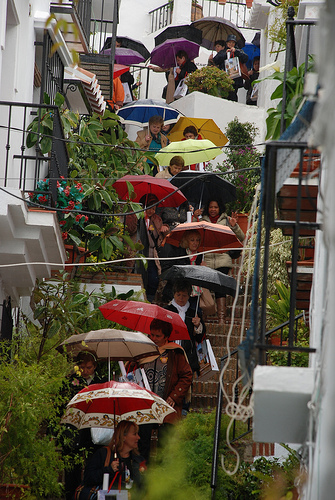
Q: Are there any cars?
A: No, there are no cars.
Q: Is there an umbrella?
A: Yes, there is an umbrella.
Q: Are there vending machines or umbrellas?
A: Yes, there is an umbrella.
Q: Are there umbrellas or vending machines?
A: Yes, there is an umbrella.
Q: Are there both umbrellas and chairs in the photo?
A: No, there is an umbrella but no chairs.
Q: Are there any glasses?
A: No, there are no glasses.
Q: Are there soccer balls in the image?
A: No, there are no soccer balls.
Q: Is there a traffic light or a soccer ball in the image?
A: No, there are no soccer balls or traffic lights.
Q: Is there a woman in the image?
A: Yes, there is a woman.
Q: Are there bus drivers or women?
A: Yes, there is a woman.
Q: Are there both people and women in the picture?
A: Yes, there are both a woman and a person.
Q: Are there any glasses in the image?
A: No, there are no glasses.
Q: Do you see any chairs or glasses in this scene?
A: No, there are no glasses or chairs.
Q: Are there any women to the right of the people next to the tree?
A: Yes, there is a woman to the right of the people.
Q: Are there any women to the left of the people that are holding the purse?
A: No, the woman is to the right of the people.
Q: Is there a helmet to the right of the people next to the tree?
A: No, there is a woman to the right of the people.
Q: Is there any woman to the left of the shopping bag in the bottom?
A: Yes, there is a woman to the left of the shopping bag.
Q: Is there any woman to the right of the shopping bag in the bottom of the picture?
A: No, the woman is to the left of the shopping bag.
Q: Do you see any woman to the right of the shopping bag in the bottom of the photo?
A: No, the woman is to the left of the shopping bag.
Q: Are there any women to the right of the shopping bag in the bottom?
A: No, the woman is to the left of the shopping bag.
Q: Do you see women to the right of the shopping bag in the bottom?
A: No, the woman is to the left of the shopping bag.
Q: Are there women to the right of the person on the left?
A: Yes, there is a woman to the right of the person.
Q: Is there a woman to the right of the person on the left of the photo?
A: Yes, there is a woman to the right of the person.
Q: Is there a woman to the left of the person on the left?
A: No, the woman is to the right of the person.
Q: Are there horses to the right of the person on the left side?
A: No, there is a woman to the right of the person.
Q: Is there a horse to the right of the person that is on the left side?
A: No, there is a woman to the right of the person.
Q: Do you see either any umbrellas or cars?
A: Yes, there is an umbrella.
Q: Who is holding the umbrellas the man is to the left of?
A: The people are holding the umbrellas.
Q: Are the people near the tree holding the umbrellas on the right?
A: Yes, the people are holding the umbrellas.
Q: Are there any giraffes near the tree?
A: No, there are people near the tree.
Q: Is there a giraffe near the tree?
A: No, there are people near the tree.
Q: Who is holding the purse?
A: The people are holding the purse.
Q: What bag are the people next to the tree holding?
A: The people are holding the purse.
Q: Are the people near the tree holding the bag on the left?
A: Yes, the people are holding the purse.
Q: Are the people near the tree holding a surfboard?
A: No, the people are holding the purse.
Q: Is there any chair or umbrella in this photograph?
A: Yes, there is an umbrella.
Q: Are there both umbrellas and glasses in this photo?
A: No, there is an umbrella but no glasses.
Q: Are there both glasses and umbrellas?
A: No, there is an umbrella but no glasses.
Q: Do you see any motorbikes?
A: No, there are no motorbikes.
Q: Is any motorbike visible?
A: No, there are no motorcycles.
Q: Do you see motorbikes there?
A: No, there are no motorbikes.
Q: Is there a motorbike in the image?
A: No, there are no motorcycles.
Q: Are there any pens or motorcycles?
A: No, there are no motorcycles or pens.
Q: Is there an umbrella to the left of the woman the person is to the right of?
A: Yes, there is an umbrella to the left of the woman.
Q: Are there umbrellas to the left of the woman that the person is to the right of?
A: Yes, there is an umbrella to the left of the woman.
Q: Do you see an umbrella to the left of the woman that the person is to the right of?
A: Yes, there is an umbrella to the left of the woman.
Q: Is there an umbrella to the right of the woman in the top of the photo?
A: No, the umbrella is to the left of the woman.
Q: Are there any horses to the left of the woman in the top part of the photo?
A: No, there is an umbrella to the left of the woman.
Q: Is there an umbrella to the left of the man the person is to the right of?
A: Yes, there is an umbrella to the left of the man.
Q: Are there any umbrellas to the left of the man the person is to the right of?
A: Yes, there is an umbrella to the left of the man.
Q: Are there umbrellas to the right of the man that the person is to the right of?
A: No, the umbrella is to the left of the man.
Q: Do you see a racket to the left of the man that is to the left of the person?
A: No, there is an umbrella to the left of the man.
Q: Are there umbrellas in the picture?
A: Yes, there is an umbrella.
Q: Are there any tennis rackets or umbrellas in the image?
A: Yes, there is an umbrella.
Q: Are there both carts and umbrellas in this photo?
A: No, there is an umbrella but no carts.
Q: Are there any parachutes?
A: No, there are no parachutes.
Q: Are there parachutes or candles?
A: No, there are no parachutes or candles.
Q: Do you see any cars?
A: No, there are no cars.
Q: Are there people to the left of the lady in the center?
A: Yes, there are people to the left of the lady.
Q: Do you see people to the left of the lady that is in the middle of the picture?
A: Yes, there are people to the left of the lady.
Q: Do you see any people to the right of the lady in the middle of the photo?
A: No, the people are to the left of the lady.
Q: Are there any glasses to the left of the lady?
A: No, there are people to the left of the lady.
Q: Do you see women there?
A: Yes, there is a woman.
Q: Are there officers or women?
A: Yes, there is a woman.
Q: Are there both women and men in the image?
A: Yes, there are both a woman and a man.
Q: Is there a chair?
A: No, there are no chairs.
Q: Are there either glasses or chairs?
A: No, there are no chairs or glasses.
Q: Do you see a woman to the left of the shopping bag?
A: Yes, there is a woman to the left of the shopping bag.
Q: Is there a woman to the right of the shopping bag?
A: No, the woman is to the left of the shopping bag.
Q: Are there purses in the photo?
A: Yes, there is a purse.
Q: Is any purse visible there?
A: Yes, there is a purse.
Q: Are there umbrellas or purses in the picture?
A: Yes, there is a purse.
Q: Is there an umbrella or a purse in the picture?
A: Yes, there is a purse.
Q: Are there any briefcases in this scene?
A: No, there are no briefcases.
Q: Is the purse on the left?
A: Yes, the purse is on the left of the image.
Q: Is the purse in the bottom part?
A: Yes, the purse is in the bottom of the image.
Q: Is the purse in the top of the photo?
A: No, the purse is in the bottom of the image.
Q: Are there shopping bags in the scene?
A: Yes, there is a shopping bag.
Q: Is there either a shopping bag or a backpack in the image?
A: Yes, there is a shopping bag.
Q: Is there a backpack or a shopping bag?
A: Yes, there is a shopping bag.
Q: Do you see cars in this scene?
A: No, there are no cars.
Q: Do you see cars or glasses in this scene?
A: No, there are no cars or glasses.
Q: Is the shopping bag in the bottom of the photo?
A: Yes, the shopping bag is in the bottom of the image.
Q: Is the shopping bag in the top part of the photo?
A: No, the shopping bag is in the bottom of the image.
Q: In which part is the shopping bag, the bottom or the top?
A: The shopping bag is in the bottom of the image.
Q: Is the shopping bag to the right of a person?
A: Yes, the shopping bag is to the right of a person.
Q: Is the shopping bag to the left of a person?
A: No, the shopping bag is to the right of a person.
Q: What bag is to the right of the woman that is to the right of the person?
A: The bag is a shopping bag.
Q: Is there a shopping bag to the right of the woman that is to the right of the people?
A: Yes, there is a shopping bag to the right of the woman.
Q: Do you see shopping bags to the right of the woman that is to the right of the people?
A: Yes, there is a shopping bag to the right of the woman.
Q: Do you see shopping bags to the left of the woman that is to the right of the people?
A: No, the shopping bag is to the right of the woman.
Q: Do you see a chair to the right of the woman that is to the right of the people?
A: No, there is a shopping bag to the right of the woman.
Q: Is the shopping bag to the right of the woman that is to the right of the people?
A: Yes, the shopping bag is to the right of the woman.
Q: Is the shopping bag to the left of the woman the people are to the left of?
A: No, the shopping bag is to the right of the woman.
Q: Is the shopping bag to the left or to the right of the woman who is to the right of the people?
A: The shopping bag is to the right of the woman.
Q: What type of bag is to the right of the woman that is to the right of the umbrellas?
A: The bag is a shopping bag.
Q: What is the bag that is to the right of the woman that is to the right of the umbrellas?
A: The bag is a shopping bag.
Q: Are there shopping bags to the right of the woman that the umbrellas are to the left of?
A: Yes, there is a shopping bag to the right of the woman.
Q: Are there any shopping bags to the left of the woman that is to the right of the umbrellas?
A: No, the shopping bag is to the right of the woman.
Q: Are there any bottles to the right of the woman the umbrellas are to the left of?
A: No, there is a shopping bag to the right of the woman.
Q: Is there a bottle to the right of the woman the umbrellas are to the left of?
A: No, there is a shopping bag to the right of the woman.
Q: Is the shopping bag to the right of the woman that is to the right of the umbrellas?
A: Yes, the shopping bag is to the right of the woman.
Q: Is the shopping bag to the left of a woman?
A: No, the shopping bag is to the right of a woman.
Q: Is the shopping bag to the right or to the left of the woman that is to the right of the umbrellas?
A: The shopping bag is to the right of the woman.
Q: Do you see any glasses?
A: No, there are no glasses.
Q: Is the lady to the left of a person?
A: Yes, the lady is to the left of a person.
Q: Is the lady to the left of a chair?
A: No, the lady is to the left of a person.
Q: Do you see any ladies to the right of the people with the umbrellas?
A: Yes, there is a lady to the right of the people.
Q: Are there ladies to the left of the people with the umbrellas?
A: No, the lady is to the right of the people.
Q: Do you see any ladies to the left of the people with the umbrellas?
A: No, the lady is to the right of the people.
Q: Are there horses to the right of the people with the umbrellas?
A: No, there is a lady to the right of the people.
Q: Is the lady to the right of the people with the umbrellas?
A: Yes, the lady is to the right of the people.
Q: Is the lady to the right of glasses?
A: No, the lady is to the right of the people.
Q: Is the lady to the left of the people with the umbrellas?
A: No, the lady is to the right of the people.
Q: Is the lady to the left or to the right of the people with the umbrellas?
A: The lady is to the right of the people.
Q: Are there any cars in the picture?
A: No, there are no cars.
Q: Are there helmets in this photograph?
A: No, there are no helmets.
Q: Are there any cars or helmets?
A: No, there are no helmets or cars.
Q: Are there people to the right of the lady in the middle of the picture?
A: Yes, there is a person to the right of the lady.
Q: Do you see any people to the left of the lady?
A: No, the person is to the right of the lady.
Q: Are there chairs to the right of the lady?
A: No, there is a person to the right of the lady.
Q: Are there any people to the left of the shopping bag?
A: Yes, there is a person to the left of the shopping bag.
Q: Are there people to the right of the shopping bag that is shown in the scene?
A: No, the person is to the left of the shopping bag.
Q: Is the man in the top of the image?
A: Yes, the man is in the top of the image.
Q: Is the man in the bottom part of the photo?
A: No, the man is in the top of the image.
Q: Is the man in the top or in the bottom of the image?
A: The man is in the top of the image.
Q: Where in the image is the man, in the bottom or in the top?
A: The man is in the top of the image.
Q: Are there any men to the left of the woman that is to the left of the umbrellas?
A: Yes, there is a man to the left of the woman.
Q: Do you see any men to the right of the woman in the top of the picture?
A: No, the man is to the left of the woman.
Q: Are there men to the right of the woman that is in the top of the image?
A: No, the man is to the left of the woman.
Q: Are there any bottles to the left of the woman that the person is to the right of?
A: No, there is a man to the left of the woman.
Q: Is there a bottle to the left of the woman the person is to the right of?
A: No, there is a man to the left of the woman.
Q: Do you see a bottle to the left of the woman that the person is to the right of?
A: No, there is a man to the left of the woman.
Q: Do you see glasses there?
A: No, there are no glasses.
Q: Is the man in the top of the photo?
A: Yes, the man is in the top of the image.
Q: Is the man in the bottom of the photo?
A: No, the man is in the top of the image.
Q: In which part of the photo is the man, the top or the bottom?
A: The man is in the top of the image.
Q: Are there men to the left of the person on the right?
A: Yes, there is a man to the left of the person.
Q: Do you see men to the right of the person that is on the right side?
A: No, the man is to the left of the person.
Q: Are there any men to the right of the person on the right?
A: No, the man is to the left of the person.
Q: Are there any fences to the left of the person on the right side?
A: No, there is a man to the left of the person.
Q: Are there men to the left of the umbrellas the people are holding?
A: Yes, there is a man to the left of the umbrellas.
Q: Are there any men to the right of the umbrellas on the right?
A: No, the man is to the left of the umbrellas.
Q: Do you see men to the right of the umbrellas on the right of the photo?
A: No, the man is to the left of the umbrellas.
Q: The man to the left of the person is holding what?
A: The man is holding the umbrella.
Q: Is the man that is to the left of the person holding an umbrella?
A: Yes, the man is holding an umbrella.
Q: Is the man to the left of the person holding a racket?
A: No, the man is holding an umbrella.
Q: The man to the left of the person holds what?
A: The man holds the umbrella.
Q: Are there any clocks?
A: No, there are no clocks.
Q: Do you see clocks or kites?
A: No, there are no clocks or kites.